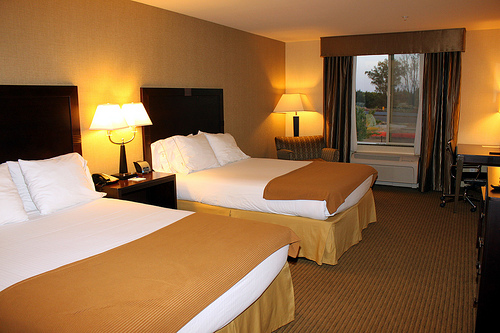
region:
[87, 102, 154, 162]
a double lamp on a table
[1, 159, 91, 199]
a set of white pillows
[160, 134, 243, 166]
four white pillows on a bed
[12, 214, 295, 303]
a brown blanket at the foot of the bed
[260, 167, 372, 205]
a folded brown blanket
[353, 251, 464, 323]
an area of brown carpet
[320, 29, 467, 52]
a brown curtain valance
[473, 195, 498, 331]
a long brown dresser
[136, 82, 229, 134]
a brown wooden headboard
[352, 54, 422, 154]
a white window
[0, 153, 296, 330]
Bed in hotel room.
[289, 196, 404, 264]
Gold dust ruffle on bed.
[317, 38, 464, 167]
Window drapes in hotel room.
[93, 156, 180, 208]
Bedside table with phone and clock.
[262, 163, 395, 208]
Gold colored blanket on bed.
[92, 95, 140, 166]
Bedside lamp with two shades.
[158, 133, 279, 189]
White sheets and white pillows.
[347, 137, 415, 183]
Heating and AC unit in hotel room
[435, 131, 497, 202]
Table and chair.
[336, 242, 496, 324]
Berber neutral colored carpet.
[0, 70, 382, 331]
two queen-sized beds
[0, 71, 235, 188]
dark brown headboards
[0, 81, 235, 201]
headboards made of wood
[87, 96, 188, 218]
nightstand between the beds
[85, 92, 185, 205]
double-shaded lamp on nightstand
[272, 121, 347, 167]
tan recliner next to bed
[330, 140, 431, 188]
air-conditioning vents by the window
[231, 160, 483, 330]
tan carpet with vertical lines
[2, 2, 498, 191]
dark beige walls and ceiling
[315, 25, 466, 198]
brown curtains around the window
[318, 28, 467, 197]
brown curtains on the window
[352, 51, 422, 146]
a window with the blinds open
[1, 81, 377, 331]
two identical hotel beds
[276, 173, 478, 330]
brown carpet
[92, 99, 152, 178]
two lamps on the nightstand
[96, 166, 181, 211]
a wooden nightstand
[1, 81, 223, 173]
two dark wooden headboards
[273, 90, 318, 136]
a lamp in the corner by the window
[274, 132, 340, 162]
an armchair by the window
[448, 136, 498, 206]
a desk by the window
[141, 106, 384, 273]
bed in hotel room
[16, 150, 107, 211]
white pillow on bed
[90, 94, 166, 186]
lit lamp on nightstand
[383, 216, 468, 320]
brown carpet floor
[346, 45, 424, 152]
window in hotel room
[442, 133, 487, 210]
office chair with wheels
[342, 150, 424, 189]
air conditioner below window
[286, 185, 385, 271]
tan colored dust ruffle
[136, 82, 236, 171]
dark colored head board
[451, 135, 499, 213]
desk in hotel room